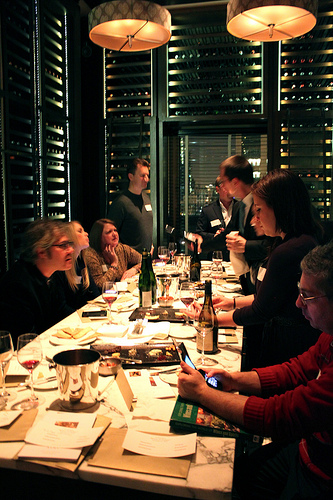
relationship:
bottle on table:
[190, 237, 200, 282] [0, 254, 251, 498]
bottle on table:
[138, 246, 155, 309] [0, 254, 251, 498]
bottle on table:
[197, 278, 219, 355] [0, 254, 251, 498]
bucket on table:
[52, 348, 99, 411] [16, 393, 193, 498]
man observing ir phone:
[179, 243, 333, 493] [177, 342, 225, 391]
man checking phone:
[179, 243, 329, 494] [178, 344, 223, 388]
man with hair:
[1, 221, 74, 351] [13, 218, 69, 265]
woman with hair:
[64, 221, 105, 319] [64, 220, 89, 291]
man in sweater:
[96, 154, 165, 260] [113, 190, 152, 254]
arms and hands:
[176, 329, 331, 438] [176, 360, 232, 407]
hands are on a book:
[176, 360, 232, 407] [168, 392, 264, 444]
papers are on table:
[5, 345, 206, 474] [0, 254, 251, 498]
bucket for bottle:
[51, 348, 99, 411] [197, 282, 218, 354]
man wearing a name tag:
[107, 157, 154, 260] [143, 200, 153, 215]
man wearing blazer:
[107, 157, 154, 260] [194, 199, 236, 247]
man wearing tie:
[216, 155, 281, 263] [233, 200, 245, 235]